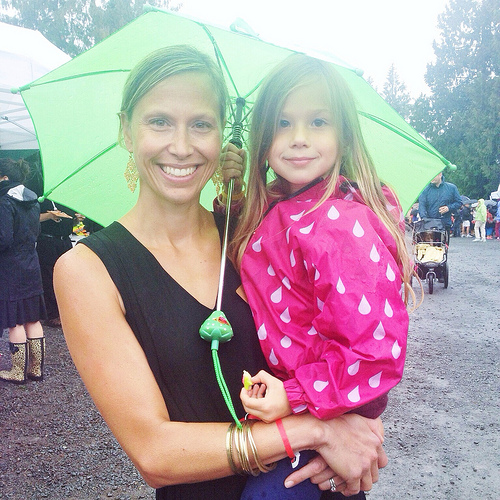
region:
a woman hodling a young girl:
[60, 32, 387, 457]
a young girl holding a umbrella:
[208, 35, 384, 257]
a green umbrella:
[32, 49, 409, 171]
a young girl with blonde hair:
[235, 67, 360, 264]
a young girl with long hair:
[235, 70, 360, 265]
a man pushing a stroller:
[409, 162, 469, 304]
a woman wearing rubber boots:
[0, 324, 52, 386]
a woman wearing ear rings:
[118, 54, 220, 224]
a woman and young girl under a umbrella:
[34, 36, 395, 237]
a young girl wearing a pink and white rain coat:
[260, 165, 370, 315]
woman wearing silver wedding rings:
[285, 418, 400, 494]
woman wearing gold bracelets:
[186, 395, 310, 482]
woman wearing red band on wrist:
[211, 392, 410, 484]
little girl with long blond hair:
[229, 33, 401, 255]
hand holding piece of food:
[188, 308, 417, 435]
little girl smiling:
[231, 41, 375, 236]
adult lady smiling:
[101, 30, 261, 227]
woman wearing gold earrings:
[88, 28, 253, 233]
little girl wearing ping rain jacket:
[225, 49, 424, 449]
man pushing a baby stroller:
[400, 145, 475, 332]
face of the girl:
[122, 83, 209, 197]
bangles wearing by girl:
[221, 428, 278, 486]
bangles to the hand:
[207, 428, 271, 485]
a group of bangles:
[213, 423, 264, 488]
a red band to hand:
[268, 424, 308, 473]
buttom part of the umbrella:
[191, 303, 269, 438]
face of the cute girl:
[255, 68, 348, 192]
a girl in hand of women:
[228, 74, 405, 487]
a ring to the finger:
[319, 471, 339, 498]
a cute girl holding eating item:
[233, 359, 275, 410]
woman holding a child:
[37, 64, 423, 491]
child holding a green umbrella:
[27, 0, 437, 280]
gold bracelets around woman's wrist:
[216, 408, 266, 488]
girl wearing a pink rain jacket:
[248, 194, 424, 428]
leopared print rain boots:
[2, 331, 50, 388]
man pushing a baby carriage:
[407, 166, 465, 298]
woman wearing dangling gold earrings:
[117, 143, 149, 210]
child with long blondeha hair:
[240, 51, 391, 284]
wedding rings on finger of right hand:
[312, 473, 347, 494]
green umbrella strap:
[211, 338, 241, 438]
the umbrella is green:
[10, 7, 478, 223]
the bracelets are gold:
[213, 415, 278, 486]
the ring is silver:
[324, 475, 338, 495]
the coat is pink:
[238, 196, 409, 408]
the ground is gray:
[429, 318, 499, 455]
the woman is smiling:
[141, 140, 220, 203]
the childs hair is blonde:
[344, 104, 364, 185]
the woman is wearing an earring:
[118, 146, 141, 196]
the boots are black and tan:
[0, 330, 48, 396]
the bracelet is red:
[270, 417, 309, 472]